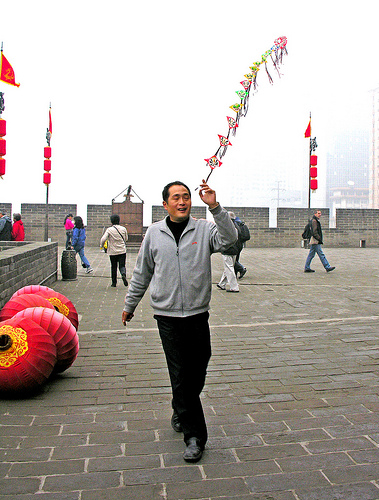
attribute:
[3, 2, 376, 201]
clouds — white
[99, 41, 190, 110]
white clouds — white 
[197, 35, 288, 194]
kite — long 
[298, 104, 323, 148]
flag — red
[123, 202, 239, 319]
sweater — gray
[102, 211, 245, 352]
sweater — grey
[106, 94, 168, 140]
clouds — white 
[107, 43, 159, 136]
sky — blue 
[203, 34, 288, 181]
kites — colorful 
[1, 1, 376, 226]
sky — blue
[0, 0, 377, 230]
cloud — white 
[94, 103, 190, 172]
sky — white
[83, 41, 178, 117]
sky — blue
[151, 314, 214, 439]
pants — black 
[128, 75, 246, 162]
clouds — white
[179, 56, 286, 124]
sky — blue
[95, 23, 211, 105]
clouds — white 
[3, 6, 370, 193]
sky — blue 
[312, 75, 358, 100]
clouds — white 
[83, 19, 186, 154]
sky — blue 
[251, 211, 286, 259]
wall —  Great Wall of China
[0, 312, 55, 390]
paper lantern — large 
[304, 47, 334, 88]
sky — blue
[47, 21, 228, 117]
clouds — white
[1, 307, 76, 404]
lantern — red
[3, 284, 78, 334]
lantern — red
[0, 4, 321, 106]
clouds — white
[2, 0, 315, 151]
clouds — white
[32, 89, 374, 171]
clouds — white 